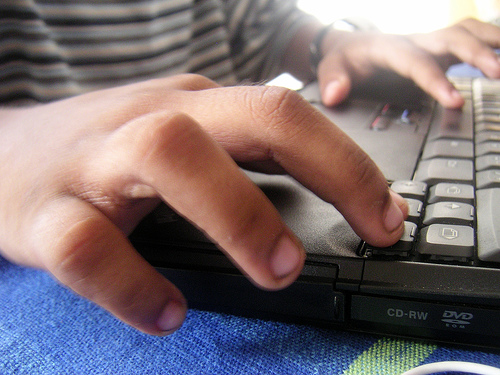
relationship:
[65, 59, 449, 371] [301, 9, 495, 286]
hands on laptop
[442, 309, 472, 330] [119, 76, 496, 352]
logo on laptop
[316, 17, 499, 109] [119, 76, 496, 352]
hand on laptop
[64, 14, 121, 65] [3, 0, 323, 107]
blue lines on striped shirt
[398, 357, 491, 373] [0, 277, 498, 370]
cord on table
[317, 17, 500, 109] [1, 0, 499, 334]
hand on person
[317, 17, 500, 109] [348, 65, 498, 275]
hand on keyboard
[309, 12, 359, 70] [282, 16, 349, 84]
watch on wrist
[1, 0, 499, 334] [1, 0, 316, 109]
person wearing shirt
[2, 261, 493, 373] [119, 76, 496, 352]
tablecloth under laptop